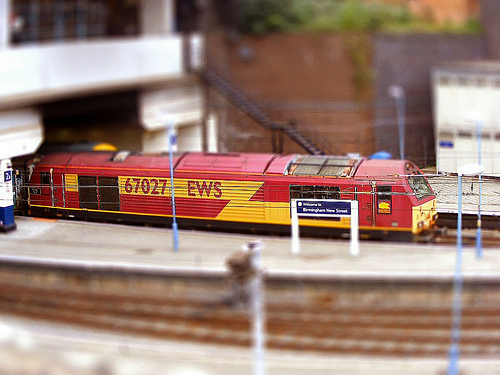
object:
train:
[0, 146, 439, 236]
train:
[25, 149, 438, 241]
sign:
[296, 201, 350, 216]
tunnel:
[12, 90, 145, 220]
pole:
[443, 170, 467, 374]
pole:
[168, 150, 180, 253]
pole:
[392, 97, 406, 159]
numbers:
[124, 178, 167, 196]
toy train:
[15, 154, 438, 237]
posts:
[290, 199, 359, 255]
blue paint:
[447, 178, 466, 365]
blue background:
[296, 201, 351, 215]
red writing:
[121, 175, 225, 200]